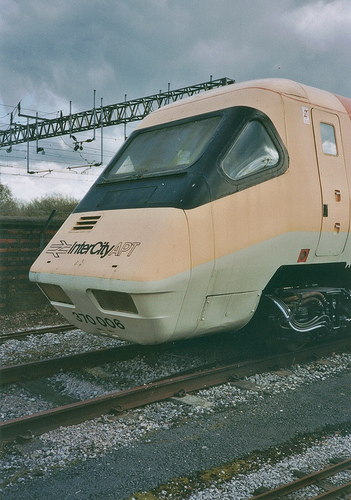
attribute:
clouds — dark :
[0, 0, 349, 209]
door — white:
[310, 103, 350, 261]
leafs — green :
[39, 190, 80, 207]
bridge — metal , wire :
[1, 74, 235, 178]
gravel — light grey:
[56, 358, 160, 397]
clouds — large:
[92, 22, 232, 82]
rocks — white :
[217, 476, 274, 491]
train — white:
[29, 78, 345, 347]